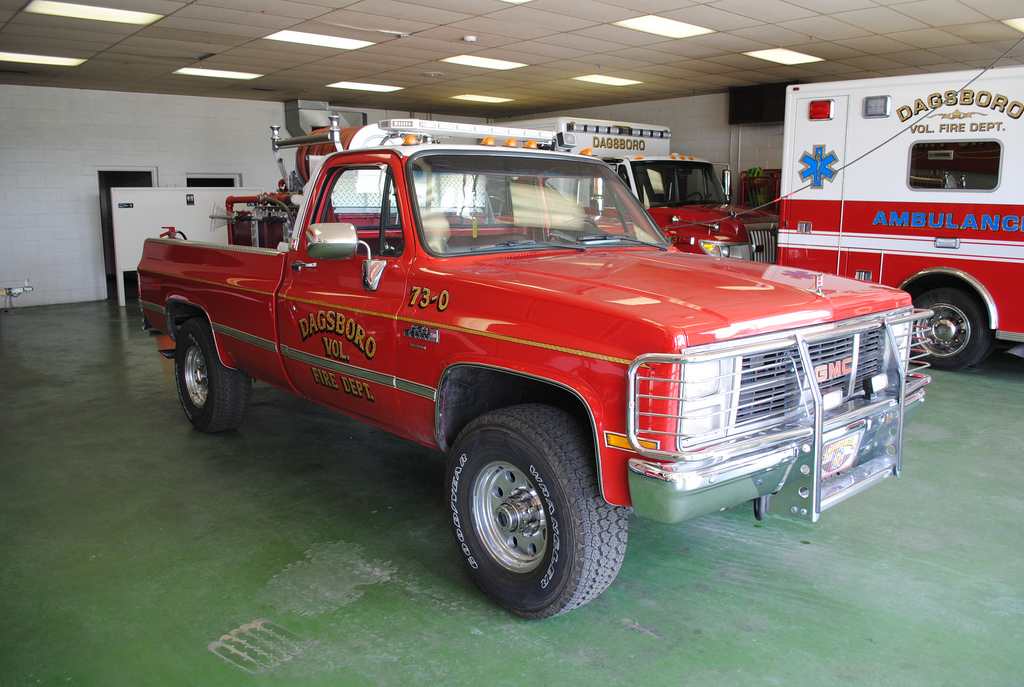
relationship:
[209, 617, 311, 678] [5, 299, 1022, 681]
tracks on floor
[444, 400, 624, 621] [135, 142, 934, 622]
tire on truck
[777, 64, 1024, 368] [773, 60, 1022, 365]
ambulance of ambulance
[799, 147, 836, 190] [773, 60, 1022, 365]
symbol on ambulance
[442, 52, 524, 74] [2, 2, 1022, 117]
light on ceiling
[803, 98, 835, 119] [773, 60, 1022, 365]
light on ambulance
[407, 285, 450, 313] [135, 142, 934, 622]
73-0 on truck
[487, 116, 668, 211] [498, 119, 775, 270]
trailer of ambulance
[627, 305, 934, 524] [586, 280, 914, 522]
bumper over bumper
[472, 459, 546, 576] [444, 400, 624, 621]
rim of tire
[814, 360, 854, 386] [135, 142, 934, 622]
gmc on truck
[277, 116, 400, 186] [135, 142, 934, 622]
hose on truck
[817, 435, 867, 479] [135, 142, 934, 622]
license plate on truck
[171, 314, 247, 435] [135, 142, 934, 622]
tire on rear of truck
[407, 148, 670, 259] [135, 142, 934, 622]
windshield of truck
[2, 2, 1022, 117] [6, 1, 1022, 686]
ceiling of garage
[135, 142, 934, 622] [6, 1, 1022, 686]
truck in garage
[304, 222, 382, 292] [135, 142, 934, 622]
mirror on truck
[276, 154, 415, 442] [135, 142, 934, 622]
door of truck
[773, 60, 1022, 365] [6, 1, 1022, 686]
ambulance in garage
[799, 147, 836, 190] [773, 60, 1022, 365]
medical symbol on ambulance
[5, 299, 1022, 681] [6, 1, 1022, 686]
floor of garage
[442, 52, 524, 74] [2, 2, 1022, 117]
light in ceiling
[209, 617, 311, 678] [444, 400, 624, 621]
tracks from tire